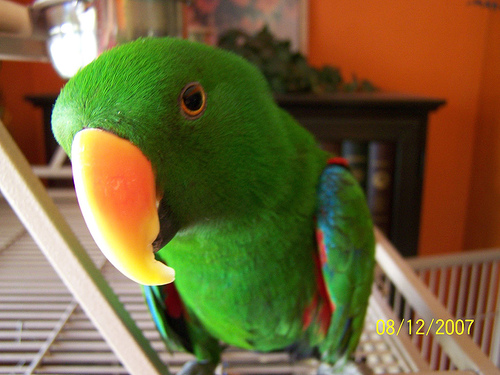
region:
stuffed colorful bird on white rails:
[20, 31, 378, 361]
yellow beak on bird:
[58, 128, 182, 295]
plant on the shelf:
[201, 23, 380, 92]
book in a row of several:
[365, 146, 389, 224]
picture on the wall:
[178, 0, 313, 57]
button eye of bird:
[164, 83, 211, 120]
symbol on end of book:
[363, 170, 393, 191]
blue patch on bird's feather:
[312, 161, 339, 221]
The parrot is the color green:
[29, 36, 423, 361]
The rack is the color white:
[6, 275, 398, 373]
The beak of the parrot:
[63, 130, 185, 291]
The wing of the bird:
[313, 155, 376, 370]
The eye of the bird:
[178, 75, 211, 122]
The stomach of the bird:
[175, 245, 310, 345]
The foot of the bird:
[168, 355, 230, 372]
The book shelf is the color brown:
[324, 88, 439, 219]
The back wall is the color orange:
[338, 2, 498, 77]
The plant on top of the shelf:
[229, 25, 386, 102]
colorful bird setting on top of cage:
[48, 39, 370, 374]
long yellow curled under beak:
[70, 126, 177, 283]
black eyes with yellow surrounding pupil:
[180, 80, 205, 116]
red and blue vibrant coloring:
[318, 158, 338, 337]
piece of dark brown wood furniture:
[20, 26, 447, 263]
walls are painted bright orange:
[309, 1, 496, 254]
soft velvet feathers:
[47, 36, 316, 346]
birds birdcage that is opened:
[353, 221, 494, 373]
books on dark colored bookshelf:
[316, 133, 393, 237]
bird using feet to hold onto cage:
[177, 333, 318, 374]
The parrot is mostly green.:
[51, 39, 375, 372]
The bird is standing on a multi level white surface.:
[1, 120, 494, 367]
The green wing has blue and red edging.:
[296, 156, 374, 368]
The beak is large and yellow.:
[71, 127, 176, 284]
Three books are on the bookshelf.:
[281, 94, 446, 249]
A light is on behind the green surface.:
[51, 4, 103, 78]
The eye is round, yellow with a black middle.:
[181, 82, 206, 114]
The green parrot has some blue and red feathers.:
[51, 35, 372, 355]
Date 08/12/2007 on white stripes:
[375, 317, 499, 332]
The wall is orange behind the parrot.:
[0, 1, 499, 253]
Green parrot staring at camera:
[30, 7, 399, 364]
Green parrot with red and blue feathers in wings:
[52, 16, 397, 370]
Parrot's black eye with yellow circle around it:
[121, 25, 232, 146]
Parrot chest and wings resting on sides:
[90, 162, 395, 362]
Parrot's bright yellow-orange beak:
[50, 92, 177, 315]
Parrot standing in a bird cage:
[10, 15, 422, 374]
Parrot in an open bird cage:
[14, 29, 495, 369]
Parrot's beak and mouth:
[62, 125, 217, 290]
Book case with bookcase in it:
[285, 36, 485, 254]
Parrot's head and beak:
[48, 32, 289, 294]